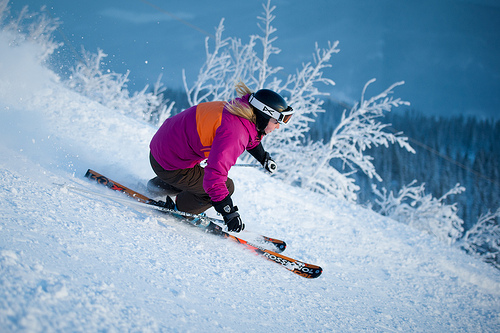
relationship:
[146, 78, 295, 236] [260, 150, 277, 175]
woman wearing glove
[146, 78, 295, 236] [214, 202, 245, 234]
woman wearing glove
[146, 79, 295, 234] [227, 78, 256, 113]
woman has hair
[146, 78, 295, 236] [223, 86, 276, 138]
woman has hair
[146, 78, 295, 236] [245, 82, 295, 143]
woman has head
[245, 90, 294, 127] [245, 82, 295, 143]
white goggles on head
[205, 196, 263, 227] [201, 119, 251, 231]
glove on arm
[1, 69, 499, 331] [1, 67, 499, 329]
snow on ground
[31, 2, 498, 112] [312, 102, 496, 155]
sky above tree line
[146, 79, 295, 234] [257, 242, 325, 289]
woman crouching on ski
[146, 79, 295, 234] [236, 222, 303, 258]
woman crouching on ski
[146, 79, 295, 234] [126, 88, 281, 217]
woman has jacket